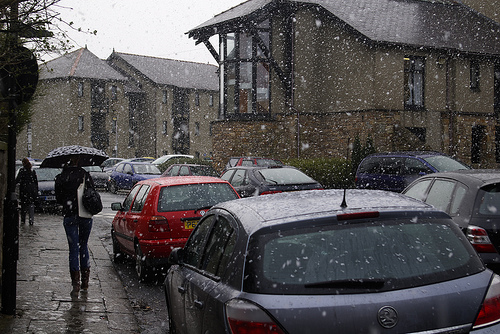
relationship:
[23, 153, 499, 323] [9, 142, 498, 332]
cars in street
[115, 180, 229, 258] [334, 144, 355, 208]
car has antennae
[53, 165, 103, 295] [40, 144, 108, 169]
woman has umbrella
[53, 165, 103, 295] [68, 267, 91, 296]
woman has boots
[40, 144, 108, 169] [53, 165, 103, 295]
umbrella over woman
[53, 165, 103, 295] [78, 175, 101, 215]
woman has purse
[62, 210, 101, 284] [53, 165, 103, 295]
jeans on woman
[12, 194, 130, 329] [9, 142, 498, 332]
sidewalk by street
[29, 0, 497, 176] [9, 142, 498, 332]
houses by street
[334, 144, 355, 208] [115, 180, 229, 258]
antennae on car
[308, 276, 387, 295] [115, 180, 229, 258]
wiper on car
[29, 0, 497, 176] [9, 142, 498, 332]
houses across street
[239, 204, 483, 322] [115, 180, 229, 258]
rear view of car